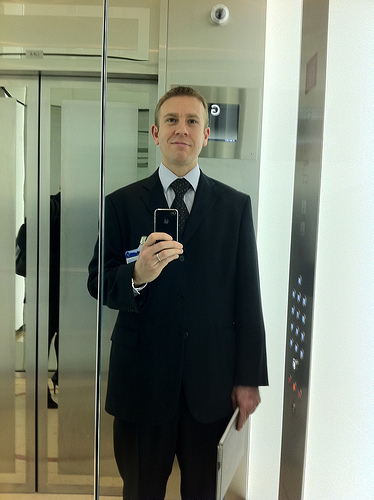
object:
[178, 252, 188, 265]
button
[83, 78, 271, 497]
man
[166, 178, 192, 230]
tie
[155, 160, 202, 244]
shirt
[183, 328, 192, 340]
button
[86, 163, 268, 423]
jacket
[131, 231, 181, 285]
hand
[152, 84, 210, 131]
hair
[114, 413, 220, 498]
pants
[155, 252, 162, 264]
ring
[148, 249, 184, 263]
finger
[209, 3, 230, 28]
camera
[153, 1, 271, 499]
wall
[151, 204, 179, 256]
phone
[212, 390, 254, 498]
pad